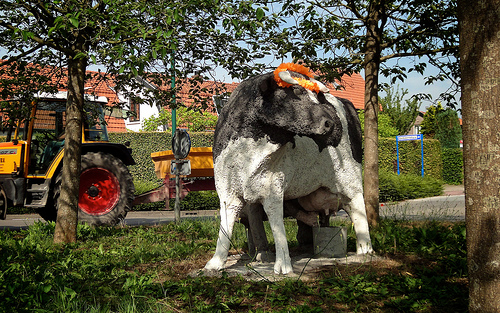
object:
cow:
[201, 62, 375, 276]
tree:
[68, 26, 171, 85]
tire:
[47, 149, 136, 233]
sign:
[395, 135, 422, 140]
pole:
[168, 47, 183, 232]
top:
[271, 64, 341, 113]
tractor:
[2, 74, 137, 233]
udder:
[317, 195, 365, 248]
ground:
[91, 230, 163, 279]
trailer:
[135, 142, 214, 213]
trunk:
[44, 95, 106, 255]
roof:
[125, 85, 172, 120]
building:
[91, 69, 216, 184]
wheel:
[79, 167, 121, 215]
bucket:
[313, 225, 347, 257]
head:
[234, 62, 337, 141]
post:
[394, 133, 425, 179]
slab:
[403, 195, 451, 235]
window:
[127, 97, 141, 122]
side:
[81, 79, 206, 141]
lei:
[274, 62, 321, 94]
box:
[151, 147, 215, 178]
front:
[202, 177, 294, 276]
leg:
[257, 197, 292, 276]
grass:
[76, 239, 154, 286]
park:
[13, 164, 191, 312]